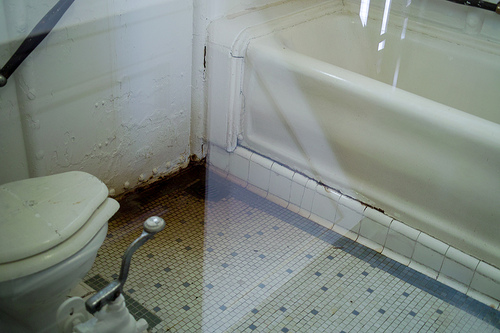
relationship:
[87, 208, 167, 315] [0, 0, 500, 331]
lever next to bathroom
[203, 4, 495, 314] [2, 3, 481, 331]
bathtub in bathroom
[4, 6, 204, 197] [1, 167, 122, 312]
wall next to toilet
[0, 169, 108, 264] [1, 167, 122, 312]
cover on toilet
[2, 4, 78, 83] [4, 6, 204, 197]
bar next to wall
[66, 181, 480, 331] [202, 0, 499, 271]
tiles below bathtub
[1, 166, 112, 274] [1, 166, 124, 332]
cover on toilet seat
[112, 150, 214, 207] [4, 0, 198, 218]
rust stain on wall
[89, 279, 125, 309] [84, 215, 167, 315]
light reflection on lever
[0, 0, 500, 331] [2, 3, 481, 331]
bathroom in bathroom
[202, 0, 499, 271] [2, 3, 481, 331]
bathtub in bathroom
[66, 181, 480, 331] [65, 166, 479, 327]
tiles on floor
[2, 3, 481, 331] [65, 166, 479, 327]
bathroom has floor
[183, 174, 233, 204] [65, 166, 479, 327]
drain in floor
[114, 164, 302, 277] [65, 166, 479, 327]
stain on floor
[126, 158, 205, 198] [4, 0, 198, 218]
rust stain on wall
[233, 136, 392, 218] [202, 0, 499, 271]
crack between bathtub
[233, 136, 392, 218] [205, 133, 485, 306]
crack between tile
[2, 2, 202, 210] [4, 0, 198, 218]
paint on wall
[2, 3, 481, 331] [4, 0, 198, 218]
bathroom has wall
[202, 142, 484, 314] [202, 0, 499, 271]
tile lining bottom of bathtub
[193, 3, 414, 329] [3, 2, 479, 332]
reflection on window glass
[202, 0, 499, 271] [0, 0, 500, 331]
bathtub in bathroom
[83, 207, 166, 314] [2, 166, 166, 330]
foot pedal on toilet